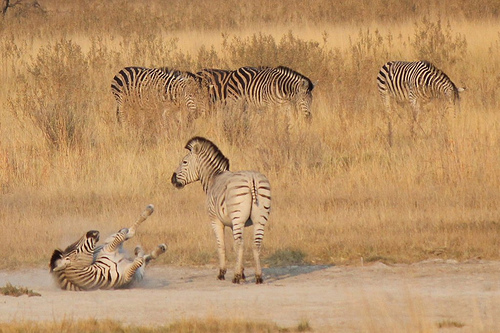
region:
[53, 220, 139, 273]
Zebra on the ground.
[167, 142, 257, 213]
Zebra looking at zebra on the ground.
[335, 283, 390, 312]
The ground is tan.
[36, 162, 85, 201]
The grass is dry.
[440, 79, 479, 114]
The zebra is eating grass.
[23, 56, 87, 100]
Weeds in the grass.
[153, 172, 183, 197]
The zebra's noise is black.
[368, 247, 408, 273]
Small patch of green grass.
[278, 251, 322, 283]
The zebra is casting a shadow.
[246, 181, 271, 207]
The zebra's tail is black and white.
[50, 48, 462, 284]
Zebra is seen.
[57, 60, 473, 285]
Six zebra is seen.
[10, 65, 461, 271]
Zebra is black and white color.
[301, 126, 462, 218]
Grass is brown color.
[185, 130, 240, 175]
Short hairs in back of zebra.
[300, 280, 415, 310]
Ground is brown color.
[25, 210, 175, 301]
One zebra is lying in ground.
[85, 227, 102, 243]
Zebra mouth is black color.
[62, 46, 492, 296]
Day time picture.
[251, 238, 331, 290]
Shadow falls on ground.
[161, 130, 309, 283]
a black and white zebra with its rear facing the camera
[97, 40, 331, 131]
three black and white zebras grazing in tall yellow grass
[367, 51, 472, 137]
one black and white zebra standing with its head down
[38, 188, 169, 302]
a black and white zebra rolling over on its back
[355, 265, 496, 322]
tan compact dirt path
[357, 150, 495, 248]
a patch of yellow grassland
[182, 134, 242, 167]
a black and white zebra mane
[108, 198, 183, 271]
four zebra hooves waving in the air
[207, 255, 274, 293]
four black zebra hooves standing on the ground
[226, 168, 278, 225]
a black and white zebra rear with a short black and white tail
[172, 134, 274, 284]
A white and black zebra.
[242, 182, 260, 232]
The tail of a zebra.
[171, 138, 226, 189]
The head of a zebra.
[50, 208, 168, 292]
A zebra lying on it's right side.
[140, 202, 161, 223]
The left hoof of a zebra.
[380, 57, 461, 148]
A different zebra on the savanna.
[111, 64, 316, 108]
Multiple zebras on the savanna.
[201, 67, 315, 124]
Zebra number one.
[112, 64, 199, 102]
Zebra number two.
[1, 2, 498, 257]
Part of the savanna above the road.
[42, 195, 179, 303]
zebra with legs in the air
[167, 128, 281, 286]
back of zebra looking left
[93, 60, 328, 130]
zebras grazing in the brush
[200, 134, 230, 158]
mane on zebra's neck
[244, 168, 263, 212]
short tail on zebra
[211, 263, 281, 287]
four hooves on the ground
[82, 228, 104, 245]
black snout of zebra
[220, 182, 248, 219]
stripes on zebra's hind quarters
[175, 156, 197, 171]
eye on zebra looking left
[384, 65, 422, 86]
stripes on zebra's torso